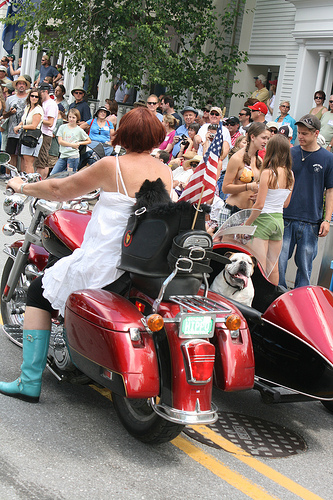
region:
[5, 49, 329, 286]
people lining the street to watch parade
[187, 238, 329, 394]
bulldog riding in a red sidecar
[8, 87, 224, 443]
biker on red motorcycle with an American flag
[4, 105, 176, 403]
biker in white sun dress, black capris and blue boots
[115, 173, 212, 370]
black cat in black seat on back of motorcycle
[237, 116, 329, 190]
three people facing each other and talking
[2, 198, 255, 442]
a red motorcycle on street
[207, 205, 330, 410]
a red motorcycle sidecar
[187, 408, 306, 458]
a closed man hole cover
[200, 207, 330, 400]
a dog riding in a sidecar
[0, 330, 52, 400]
a light blue boot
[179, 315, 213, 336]
a motorcycle license plate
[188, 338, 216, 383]
a red motorcycle brake light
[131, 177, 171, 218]
a black cat riding on motorcycle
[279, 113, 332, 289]
a young man on sidewalk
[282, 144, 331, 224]
a dark blue t-shirt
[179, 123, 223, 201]
a small American flag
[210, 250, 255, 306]
a dog with it's tongue hanging out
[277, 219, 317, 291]
a pair of worn jeans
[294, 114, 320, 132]
a brown hat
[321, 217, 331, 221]
a metal wrist watch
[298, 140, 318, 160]
a man's neck chain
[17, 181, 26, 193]
a metal wrist watch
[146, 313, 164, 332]
a motorcycle left turn signal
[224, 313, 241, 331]
a motorcycle right turn signal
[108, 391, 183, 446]
a motorcycle rear tire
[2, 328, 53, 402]
woman wearing long blue boots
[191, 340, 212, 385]
red tail light on the back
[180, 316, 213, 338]
tag on the back of bike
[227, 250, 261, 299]
dog on the inside of the bike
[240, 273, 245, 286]
dog tongue hanging out the mouth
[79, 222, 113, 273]
lady has on a white dress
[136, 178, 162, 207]
cat on the lady back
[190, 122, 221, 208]
flag attached to the bike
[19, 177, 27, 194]
woman has on a watch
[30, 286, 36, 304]
lady has on black leggings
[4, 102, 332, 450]
woman riding red motorcycle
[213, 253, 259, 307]
bulldog riding in the sidecar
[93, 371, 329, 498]
double yellow lines on the street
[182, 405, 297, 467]
manhole cover on the street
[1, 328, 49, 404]
blue boot woman is wearing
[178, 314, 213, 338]
license plate on the motorcycle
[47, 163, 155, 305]
white dress the woman is wearing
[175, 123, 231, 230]
american flag on the back of the motorcycle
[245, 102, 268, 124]
man wearing red hat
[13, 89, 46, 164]
woman with black handbag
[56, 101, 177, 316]
A woman riding a bike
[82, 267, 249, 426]
A motorbike on the road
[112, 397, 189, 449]
Wheel of a bike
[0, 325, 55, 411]
Blue and black boots